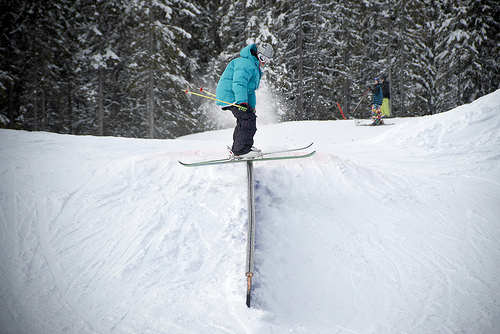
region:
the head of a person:
[252, 37, 281, 72]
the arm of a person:
[230, 58, 258, 100]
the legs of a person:
[229, 102, 264, 149]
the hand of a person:
[237, 96, 253, 116]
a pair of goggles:
[257, 50, 275, 65]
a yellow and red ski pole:
[175, 85, 259, 113]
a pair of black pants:
[226, 101, 262, 154]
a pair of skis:
[175, 138, 325, 174]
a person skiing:
[206, 35, 295, 161]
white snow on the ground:
[0, 87, 499, 332]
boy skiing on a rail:
[156, 30, 333, 195]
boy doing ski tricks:
[168, 26, 320, 176]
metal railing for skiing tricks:
[233, 168, 270, 310]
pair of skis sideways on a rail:
[179, 140, 324, 174]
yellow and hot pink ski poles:
[178, 81, 249, 116]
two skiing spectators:
[333, 60, 401, 137]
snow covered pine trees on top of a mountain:
[23, 14, 182, 114]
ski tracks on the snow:
[33, 161, 171, 296]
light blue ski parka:
[216, 55, 270, 113]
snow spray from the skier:
[261, 92, 298, 122]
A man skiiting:
[178, 40, 320, 166]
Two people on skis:
[351, 73, 401, 125]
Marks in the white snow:
[17, 168, 212, 321]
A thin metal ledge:
[225, 160, 275, 310]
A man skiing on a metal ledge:
[179, 38, 319, 305]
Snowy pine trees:
[21, 0, 195, 127]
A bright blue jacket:
[214, 52, 256, 108]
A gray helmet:
[254, 40, 276, 65]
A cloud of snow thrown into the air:
[254, 77, 294, 129]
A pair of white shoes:
[232, 145, 267, 160]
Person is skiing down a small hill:
[156, 21, 326, 184]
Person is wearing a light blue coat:
[195, 41, 285, 114]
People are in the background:
[356, 70, 408, 135]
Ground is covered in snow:
[0, 133, 498, 323]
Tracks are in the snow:
[41, 159, 214, 293]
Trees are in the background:
[3, 2, 499, 109]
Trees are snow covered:
[0, 0, 497, 119]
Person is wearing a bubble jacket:
[197, 38, 284, 118]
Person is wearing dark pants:
[217, 99, 264, 158]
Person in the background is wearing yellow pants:
[373, 93, 395, 120]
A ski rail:
[243, 157, 270, 310]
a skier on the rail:
[186, 34, 338, 186]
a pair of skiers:
[352, 70, 410, 134]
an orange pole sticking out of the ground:
[330, 99, 350, 121]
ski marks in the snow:
[33, 145, 435, 332]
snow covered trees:
[24, 10, 482, 108]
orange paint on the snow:
[158, 139, 351, 167]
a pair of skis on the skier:
[175, 135, 327, 182]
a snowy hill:
[376, 80, 499, 150]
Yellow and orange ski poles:
[167, 83, 257, 117]